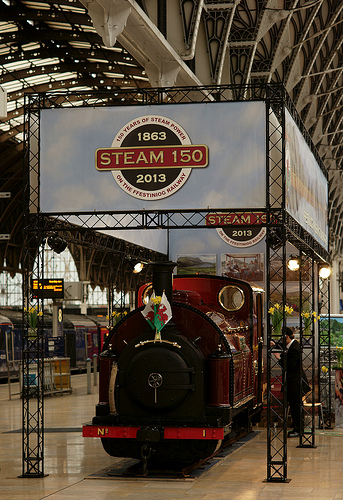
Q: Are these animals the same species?
A: Yes, all the animals are dragons.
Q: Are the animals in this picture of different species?
A: No, all the animals are dragons.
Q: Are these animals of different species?
A: No, all the animals are dragons.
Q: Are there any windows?
A: Yes, there is a window.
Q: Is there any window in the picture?
A: Yes, there is a window.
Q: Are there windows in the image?
A: Yes, there is a window.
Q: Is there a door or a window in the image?
A: Yes, there is a window.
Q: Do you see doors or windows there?
A: Yes, there is a window.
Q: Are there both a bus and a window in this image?
A: No, there is a window but no buses.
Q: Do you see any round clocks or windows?
A: Yes, there is a round window.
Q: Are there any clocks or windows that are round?
A: Yes, the window is round.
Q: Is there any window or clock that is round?
A: Yes, the window is round.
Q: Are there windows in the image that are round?
A: Yes, there is a round window.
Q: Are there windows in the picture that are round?
A: Yes, there is a window that is round.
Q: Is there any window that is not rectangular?
A: Yes, there is a round window.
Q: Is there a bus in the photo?
A: No, there are no buses.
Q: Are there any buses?
A: No, there are no buses.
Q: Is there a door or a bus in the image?
A: No, there are no buses or doors.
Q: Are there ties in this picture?
A: No, there are no ties.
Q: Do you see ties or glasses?
A: No, there are no ties or glasses.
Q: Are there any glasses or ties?
A: No, there are no ties or glasses.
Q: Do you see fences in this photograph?
A: No, there are no fences.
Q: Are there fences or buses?
A: No, there are no fences or buses.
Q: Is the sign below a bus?
A: No, the sign is below the train.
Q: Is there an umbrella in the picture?
A: No, there are no umbrellas.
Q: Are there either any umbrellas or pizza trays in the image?
A: No, there are no umbrellas or pizza trays.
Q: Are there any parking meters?
A: No, there are no parking meters.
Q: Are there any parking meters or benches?
A: No, there are no parking meters or benches.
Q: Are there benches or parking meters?
A: No, there are no parking meters or benches.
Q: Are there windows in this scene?
A: Yes, there is a window.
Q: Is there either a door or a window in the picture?
A: Yes, there is a window.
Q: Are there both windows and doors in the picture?
A: No, there is a window but no doors.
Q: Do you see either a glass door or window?
A: Yes, there is a glass window.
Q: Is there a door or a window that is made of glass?
A: Yes, the window is made of glass.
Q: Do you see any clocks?
A: No, there are no clocks.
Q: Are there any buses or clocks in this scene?
A: No, there are no clocks or buses.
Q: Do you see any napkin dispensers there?
A: No, there are no napkin dispensers.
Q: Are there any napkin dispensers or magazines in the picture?
A: No, there are no napkin dispensers or magazines.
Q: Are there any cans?
A: No, there are no cans.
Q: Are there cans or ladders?
A: No, there are no cans or ladders.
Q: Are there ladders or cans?
A: No, there are no cans or ladders.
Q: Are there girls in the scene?
A: No, there are no girls.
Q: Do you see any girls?
A: No, there are no girls.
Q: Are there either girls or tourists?
A: No, there are no girls or tourists.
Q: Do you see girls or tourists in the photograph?
A: No, there are no girls or tourists.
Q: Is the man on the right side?
A: Yes, the man is on the right of the image.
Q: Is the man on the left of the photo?
A: No, the man is on the right of the image.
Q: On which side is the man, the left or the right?
A: The man is on the right of the image.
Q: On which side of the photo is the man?
A: The man is on the right of the image.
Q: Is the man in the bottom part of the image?
A: Yes, the man is in the bottom of the image.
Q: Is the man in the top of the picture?
A: No, the man is in the bottom of the image.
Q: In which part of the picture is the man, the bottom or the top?
A: The man is in the bottom of the image.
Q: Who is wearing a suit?
A: The man is wearing a suit.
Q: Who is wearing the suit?
A: The man is wearing a suit.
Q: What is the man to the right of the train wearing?
A: The man is wearing a suit.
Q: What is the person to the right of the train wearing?
A: The man is wearing a suit.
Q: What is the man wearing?
A: The man is wearing a suit.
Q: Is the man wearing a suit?
A: Yes, the man is wearing a suit.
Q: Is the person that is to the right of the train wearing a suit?
A: Yes, the man is wearing a suit.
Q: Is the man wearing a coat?
A: No, the man is wearing a suit.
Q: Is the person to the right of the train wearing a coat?
A: No, the man is wearing a suit.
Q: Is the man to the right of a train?
A: Yes, the man is to the right of a train.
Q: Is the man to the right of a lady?
A: No, the man is to the right of a train.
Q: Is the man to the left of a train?
A: No, the man is to the right of a train.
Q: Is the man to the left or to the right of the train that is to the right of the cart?
A: The man is to the right of the train.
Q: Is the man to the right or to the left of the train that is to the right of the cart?
A: The man is to the right of the train.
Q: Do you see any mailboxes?
A: No, there are no mailboxes.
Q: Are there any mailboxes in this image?
A: No, there are no mailboxes.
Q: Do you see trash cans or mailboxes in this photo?
A: No, there are no mailboxes or trash cans.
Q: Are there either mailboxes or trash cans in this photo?
A: No, there are no mailboxes or trash cans.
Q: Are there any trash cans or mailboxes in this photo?
A: No, there are no mailboxes or trash cans.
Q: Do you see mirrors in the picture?
A: No, there are no mirrors.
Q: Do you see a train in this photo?
A: Yes, there is a train.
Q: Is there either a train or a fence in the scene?
A: Yes, there is a train.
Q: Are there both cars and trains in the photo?
A: No, there is a train but no cars.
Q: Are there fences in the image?
A: No, there are no fences.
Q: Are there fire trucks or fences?
A: No, there are no fences or fire trucks.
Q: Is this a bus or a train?
A: This is a train.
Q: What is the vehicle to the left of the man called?
A: The vehicle is a train.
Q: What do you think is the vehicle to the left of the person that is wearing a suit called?
A: The vehicle is a train.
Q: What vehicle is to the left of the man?
A: The vehicle is a train.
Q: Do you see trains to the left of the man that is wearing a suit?
A: Yes, there is a train to the left of the man.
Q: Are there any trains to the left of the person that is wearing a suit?
A: Yes, there is a train to the left of the man.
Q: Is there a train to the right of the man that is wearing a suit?
A: No, the train is to the left of the man.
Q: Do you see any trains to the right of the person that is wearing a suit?
A: No, the train is to the left of the man.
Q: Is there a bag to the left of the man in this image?
A: No, there is a train to the left of the man.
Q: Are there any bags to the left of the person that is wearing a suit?
A: No, there is a train to the left of the man.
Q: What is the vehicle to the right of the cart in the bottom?
A: The vehicle is a train.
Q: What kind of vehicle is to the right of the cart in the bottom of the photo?
A: The vehicle is a train.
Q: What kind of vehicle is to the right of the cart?
A: The vehicle is a train.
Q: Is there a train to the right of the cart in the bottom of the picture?
A: Yes, there is a train to the right of the cart.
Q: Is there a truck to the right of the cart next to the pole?
A: No, there is a train to the right of the cart.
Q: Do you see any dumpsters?
A: No, there are no dumpsters.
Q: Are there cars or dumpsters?
A: No, there are no dumpsters or cars.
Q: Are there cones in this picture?
A: No, there are no cones.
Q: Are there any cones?
A: No, there are no cones.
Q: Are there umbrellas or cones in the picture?
A: No, there are no cones or umbrellas.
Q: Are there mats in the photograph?
A: No, there are no mats.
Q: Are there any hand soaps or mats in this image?
A: No, there are no mats or hand soaps.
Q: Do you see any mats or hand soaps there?
A: No, there are no mats or hand soaps.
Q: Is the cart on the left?
A: Yes, the cart is on the left of the image.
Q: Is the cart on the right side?
A: No, the cart is on the left of the image.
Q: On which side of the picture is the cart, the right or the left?
A: The cart is on the left of the image.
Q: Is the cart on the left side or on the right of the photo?
A: The cart is on the left of the image.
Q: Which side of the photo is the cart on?
A: The cart is on the left of the image.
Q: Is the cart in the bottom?
A: Yes, the cart is in the bottom of the image.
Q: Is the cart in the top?
A: No, the cart is in the bottom of the image.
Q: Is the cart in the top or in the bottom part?
A: The cart is in the bottom of the image.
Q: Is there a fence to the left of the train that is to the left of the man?
A: No, there is a cart to the left of the train.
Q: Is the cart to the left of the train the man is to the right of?
A: Yes, the cart is to the left of the train.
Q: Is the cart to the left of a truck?
A: No, the cart is to the left of the train.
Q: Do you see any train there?
A: Yes, there is a train.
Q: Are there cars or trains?
A: Yes, there is a train.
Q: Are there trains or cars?
A: Yes, there is a train.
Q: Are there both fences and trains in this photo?
A: No, there is a train but no fences.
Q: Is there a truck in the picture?
A: No, there are no trucks.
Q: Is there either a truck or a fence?
A: No, there are no trucks or fences.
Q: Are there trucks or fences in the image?
A: No, there are no trucks or fences.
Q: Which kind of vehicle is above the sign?
A: The vehicle is a train.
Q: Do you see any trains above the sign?
A: Yes, there is a train above the sign.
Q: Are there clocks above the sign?
A: No, there is a train above the sign.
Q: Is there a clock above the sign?
A: No, there is a train above the sign.